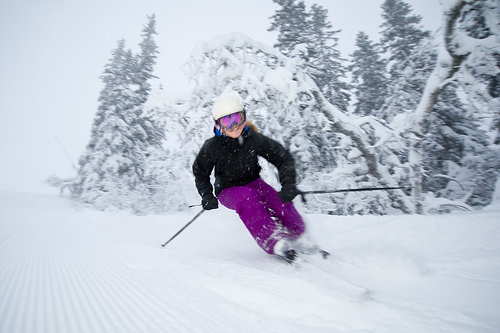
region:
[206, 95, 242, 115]
The white helmet on the skier.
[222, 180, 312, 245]
The purple pants the skier is wearing.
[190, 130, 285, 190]
The black coat the skier is wearing.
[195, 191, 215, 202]
The glove on the skier's left hand.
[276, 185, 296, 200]
The glove on the skier's right hand.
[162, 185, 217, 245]
The ski pole in the skier's left hand.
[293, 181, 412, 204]
The ski pole in the skier's right hand.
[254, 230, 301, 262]
The skier's left boot.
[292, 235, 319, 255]
The skier's right boot.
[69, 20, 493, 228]
The snow covered trees behind the skier.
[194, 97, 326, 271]
young girl skiing down snowy moutain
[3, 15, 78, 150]
white clouds against sky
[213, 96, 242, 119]
young girl wearing white helmet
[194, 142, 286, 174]
young girl wearing black jacket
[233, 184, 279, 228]
young girl wearing purple pants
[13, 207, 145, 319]
white snow on mountain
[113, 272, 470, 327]
white snow on mountain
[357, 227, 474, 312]
white snow on mountain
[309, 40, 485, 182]
green trees covered with white snow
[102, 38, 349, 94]
green trees covered with white snow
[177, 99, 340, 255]
A young girl skiing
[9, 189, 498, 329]
The ground covered in snow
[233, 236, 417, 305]
A pair of skis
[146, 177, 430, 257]
a pair of ski poles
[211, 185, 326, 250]
purple snow pants on the skiier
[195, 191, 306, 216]
black gloves on the skiier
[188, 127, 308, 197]
A black jacket on the skiier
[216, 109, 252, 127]
purple goggles on the skiier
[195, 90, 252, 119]
a white helmet on the skiier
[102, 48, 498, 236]
trees covered in snow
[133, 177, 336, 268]
purple ski pants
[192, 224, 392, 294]
ski shoes on skiers foot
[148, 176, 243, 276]
someone holding ski stick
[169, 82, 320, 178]
ski helmet on someone head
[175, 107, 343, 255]
black ski jacket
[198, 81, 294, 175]
pink and purple ski gogglrs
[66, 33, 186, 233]
tree covered in snow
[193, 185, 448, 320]
snow under skiers feet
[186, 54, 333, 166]
white ski helmet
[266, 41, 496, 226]
tree with no leaves covered in snow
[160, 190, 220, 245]
Skiing pole held by girl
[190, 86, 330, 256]
Young girl is skiing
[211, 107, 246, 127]
Purple goggles on girls head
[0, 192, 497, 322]
Snowy slopes and mounds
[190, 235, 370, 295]
White ski's camouflaged in the snow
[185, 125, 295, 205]
Black thermal jacket to keep warm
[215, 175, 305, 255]
Purple thermal pants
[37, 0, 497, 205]
Snowy, filled forest.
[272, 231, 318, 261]
White ski boots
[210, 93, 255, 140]
White skiing helmet